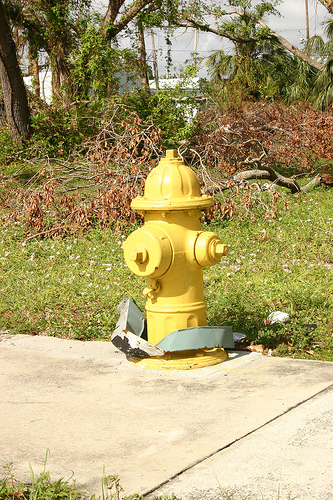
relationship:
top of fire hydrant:
[130, 142, 205, 200] [137, 151, 225, 374]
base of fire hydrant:
[131, 322, 230, 371] [137, 151, 225, 374]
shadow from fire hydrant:
[216, 285, 325, 344] [137, 151, 225, 374]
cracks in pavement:
[118, 363, 332, 498] [2, 329, 333, 500]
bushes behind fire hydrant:
[8, 94, 333, 152] [137, 151, 225, 374]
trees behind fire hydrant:
[2, 3, 268, 131] [137, 151, 225, 374]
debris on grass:
[25, 114, 296, 315] [1, 131, 333, 356]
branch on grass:
[20, 122, 323, 224] [1, 131, 333, 356]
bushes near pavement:
[8, 94, 333, 152] [2, 329, 333, 500]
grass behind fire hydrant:
[1, 131, 333, 356] [137, 151, 225, 374]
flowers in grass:
[14, 233, 126, 288] [1, 131, 333, 356]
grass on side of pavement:
[1, 131, 333, 356] [2, 329, 333, 500]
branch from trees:
[20, 122, 323, 224] [2, 3, 268, 131]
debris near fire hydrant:
[25, 114, 296, 315] [137, 151, 225, 374]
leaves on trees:
[24, 6, 329, 97] [2, 3, 268, 131]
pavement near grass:
[2, 329, 333, 500] [1, 131, 333, 356]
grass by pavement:
[1, 131, 333, 356] [2, 329, 333, 500]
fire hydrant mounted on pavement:
[137, 151, 225, 374] [2, 329, 333, 500]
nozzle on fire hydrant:
[122, 231, 163, 278] [137, 151, 225, 374]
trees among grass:
[2, 3, 268, 131] [1, 131, 333, 356]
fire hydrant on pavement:
[137, 151, 225, 374] [2, 329, 333, 500]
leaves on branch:
[23, 107, 225, 221] [20, 122, 323, 224]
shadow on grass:
[216, 285, 325, 344] [1, 131, 333, 356]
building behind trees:
[32, 61, 216, 116] [2, 3, 268, 131]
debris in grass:
[25, 114, 296, 315] [1, 131, 333, 356]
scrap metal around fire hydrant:
[112, 294, 237, 363] [137, 151, 225, 374]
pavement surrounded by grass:
[2, 329, 333, 500] [1, 131, 333, 356]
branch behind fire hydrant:
[20, 122, 323, 224] [137, 151, 225, 374]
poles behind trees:
[24, 6, 329, 97] [2, 3, 268, 131]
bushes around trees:
[8, 94, 333, 152] [2, 3, 268, 131]